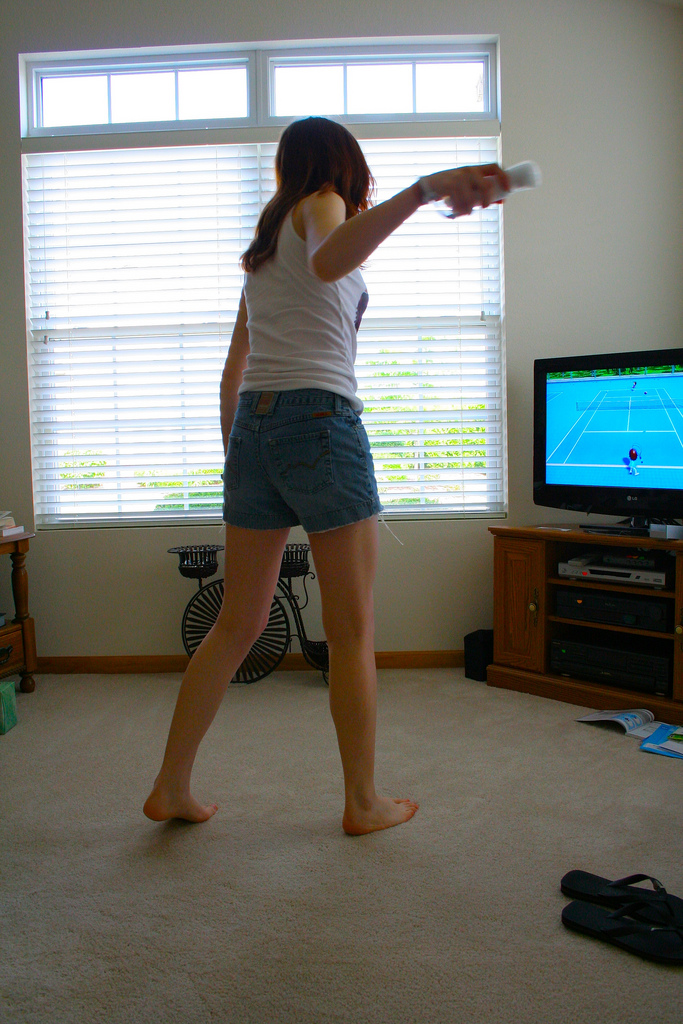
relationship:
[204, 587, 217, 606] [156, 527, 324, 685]
metal bar on decoration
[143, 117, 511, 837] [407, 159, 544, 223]
girl holding remote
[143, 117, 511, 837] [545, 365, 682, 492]
girl playing tv screen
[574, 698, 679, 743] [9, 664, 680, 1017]
book on floor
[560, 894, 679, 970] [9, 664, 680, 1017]
flip flop on floor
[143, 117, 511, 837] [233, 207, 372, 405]
girl wearing shirt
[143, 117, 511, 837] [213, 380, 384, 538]
girl wearing shorts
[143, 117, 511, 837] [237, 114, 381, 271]
girl has hair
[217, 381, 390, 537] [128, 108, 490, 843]
jean shorts of woman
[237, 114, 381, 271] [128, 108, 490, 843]
hair of woman